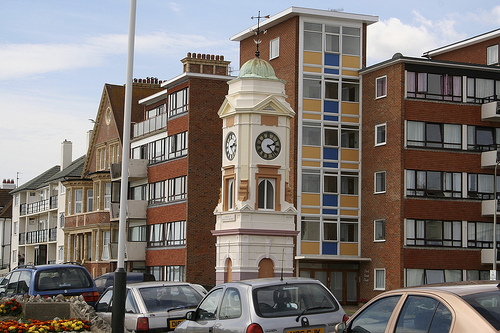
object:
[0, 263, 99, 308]
van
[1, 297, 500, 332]
road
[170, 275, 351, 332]
car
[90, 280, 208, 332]
car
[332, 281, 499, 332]
car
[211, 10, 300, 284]
tower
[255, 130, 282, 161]
clock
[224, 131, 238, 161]
clock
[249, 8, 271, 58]
vane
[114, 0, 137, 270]
pole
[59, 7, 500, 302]
building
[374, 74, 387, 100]
window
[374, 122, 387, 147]
window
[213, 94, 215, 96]
bricks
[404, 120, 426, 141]
windows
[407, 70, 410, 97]
curtains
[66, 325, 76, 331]
flowers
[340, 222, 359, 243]
windows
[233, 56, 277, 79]
top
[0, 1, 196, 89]
sky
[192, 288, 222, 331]
door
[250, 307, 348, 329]
door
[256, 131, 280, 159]
clockface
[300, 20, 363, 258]
facade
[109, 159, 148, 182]
balconies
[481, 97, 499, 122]
balconies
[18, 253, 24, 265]
person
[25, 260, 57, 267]
balcony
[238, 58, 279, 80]
dome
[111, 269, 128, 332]
base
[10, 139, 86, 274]
building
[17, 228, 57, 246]
fence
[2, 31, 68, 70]
cloud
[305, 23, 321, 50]
curtain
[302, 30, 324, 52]
window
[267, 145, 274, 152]
hands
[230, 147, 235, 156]
hands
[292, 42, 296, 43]
brick